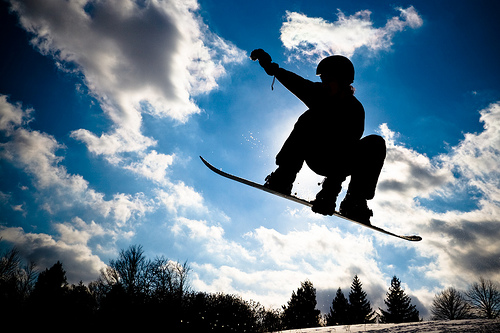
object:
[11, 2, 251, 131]
cloud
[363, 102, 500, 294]
cloud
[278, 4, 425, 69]
cloud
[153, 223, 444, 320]
cloud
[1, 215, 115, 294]
cloud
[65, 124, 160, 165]
cloud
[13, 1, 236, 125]
section